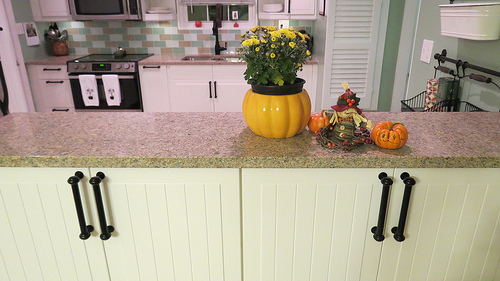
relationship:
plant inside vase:
[230, 20, 310, 86] [240, 86, 313, 133]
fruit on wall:
[189, 20, 202, 30] [31, 7, 296, 57]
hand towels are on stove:
[71, 74, 131, 109] [72, 37, 149, 114]